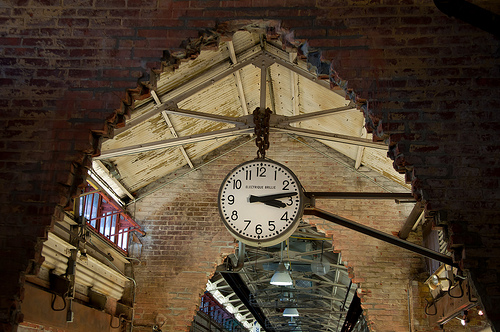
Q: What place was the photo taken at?
A: It was taken at the entrance.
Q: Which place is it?
A: It is an entrance.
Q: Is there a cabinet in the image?
A: No, there are no cabinets.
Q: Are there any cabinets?
A: No, there are no cabinets.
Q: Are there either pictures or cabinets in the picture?
A: No, there are no cabinets or pictures.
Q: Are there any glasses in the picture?
A: No, there are no glasses.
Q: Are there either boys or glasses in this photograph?
A: No, there are no glasses or boys.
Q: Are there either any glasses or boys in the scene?
A: No, there are no glasses or boys.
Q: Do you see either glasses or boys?
A: No, there are no glasses or boys.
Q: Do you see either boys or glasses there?
A: No, there are no glasses or boys.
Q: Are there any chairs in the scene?
A: No, there are no chairs.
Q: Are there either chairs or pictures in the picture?
A: No, there are no chairs or pictures.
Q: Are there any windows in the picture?
A: Yes, there is a window.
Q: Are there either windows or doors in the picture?
A: Yes, there is a window.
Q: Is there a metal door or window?
A: Yes, there is a metal window.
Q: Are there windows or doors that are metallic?
A: Yes, the window is metallic.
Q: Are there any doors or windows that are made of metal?
A: Yes, the window is made of metal.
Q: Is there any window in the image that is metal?
A: Yes, there is a metal window.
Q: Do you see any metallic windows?
A: Yes, there is a metal window.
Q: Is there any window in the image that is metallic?
A: Yes, there is a window that is metallic.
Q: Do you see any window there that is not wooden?
A: Yes, there is a metallic window.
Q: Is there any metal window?
A: Yes, there is a window that is made of metal.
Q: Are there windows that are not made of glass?
A: Yes, there is a window that is made of metal.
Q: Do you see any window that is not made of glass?
A: Yes, there is a window that is made of metal.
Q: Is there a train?
A: No, there are no trains.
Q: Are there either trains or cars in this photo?
A: No, there are no trains or cars.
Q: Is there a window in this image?
A: Yes, there is a window.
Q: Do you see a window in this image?
A: Yes, there is a window.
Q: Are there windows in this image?
A: Yes, there is a window.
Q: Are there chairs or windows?
A: Yes, there is a window.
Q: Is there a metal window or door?
A: Yes, there is a metal window.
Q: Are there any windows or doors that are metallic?
A: Yes, the window is metallic.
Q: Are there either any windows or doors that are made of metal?
A: Yes, the window is made of metal.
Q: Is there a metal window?
A: Yes, there is a window that is made of metal.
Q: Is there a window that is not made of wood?
A: Yes, there is a window that is made of metal.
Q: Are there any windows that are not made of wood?
A: Yes, there is a window that is made of metal.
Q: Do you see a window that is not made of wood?
A: Yes, there is a window that is made of metal.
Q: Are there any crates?
A: No, there are no crates.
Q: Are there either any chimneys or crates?
A: No, there are no crates or chimneys.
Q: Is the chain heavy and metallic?
A: Yes, the chain is heavy and metallic.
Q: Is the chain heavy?
A: Yes, the chain is heavy.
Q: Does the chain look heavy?
A: Yes, the chain is heavy.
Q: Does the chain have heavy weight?
A: Yes, the chain is heavy.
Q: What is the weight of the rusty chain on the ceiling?
A: The chain is heavy.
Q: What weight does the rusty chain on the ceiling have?
A: The chain has heavy weight.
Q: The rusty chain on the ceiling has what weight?
A: The chain is heavy.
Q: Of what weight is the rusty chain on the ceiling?
A: The chain is heavy.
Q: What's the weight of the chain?
A: The chain is heavy.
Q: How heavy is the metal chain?
A: The chain is heavy.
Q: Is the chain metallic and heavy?
A: Yes, the chain is metallic and heavy.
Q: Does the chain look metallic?
A: Yes, the chain is metallic.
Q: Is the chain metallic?
A: Yes, the chain is metallic.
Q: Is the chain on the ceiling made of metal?
A: Yes, the chain is made of metal.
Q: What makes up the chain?
A: The chain is made of metal.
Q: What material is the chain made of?
A: The chain is made of metal.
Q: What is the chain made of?
A: The chain is made of metal.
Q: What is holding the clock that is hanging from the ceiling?
A: The chain is holding the clock.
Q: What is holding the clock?
A: The chain is holding the clock.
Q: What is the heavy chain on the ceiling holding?
A: The chain is holding the clock.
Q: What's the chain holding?
A: The chain is holding the clock.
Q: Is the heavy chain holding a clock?
A: Yes, the chain is holding a clock.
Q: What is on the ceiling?
A: The chain is on the ceiling.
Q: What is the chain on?
A: The chain is on the ceiling.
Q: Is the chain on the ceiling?
A: Yes, the chain is on the ceiling.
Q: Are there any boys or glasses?
A: No, there are no glasses or boys.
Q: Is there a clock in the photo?
A: Yes, there is a clock.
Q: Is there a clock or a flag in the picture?
A: Yes, there is a clock.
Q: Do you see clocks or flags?
A: Yes, there is a clock.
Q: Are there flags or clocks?
A: Yes, there is a clock.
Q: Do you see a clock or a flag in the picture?
A: Yes, there is a clock.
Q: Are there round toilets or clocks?
A: Yes, there is a round clock.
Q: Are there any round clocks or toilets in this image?
A: Yes, there is a round clock.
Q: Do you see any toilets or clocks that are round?
A: Yes, the clock is round.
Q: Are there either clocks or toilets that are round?
A: Yes, the clock is round.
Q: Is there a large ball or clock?
A: Yes, there is a large clock.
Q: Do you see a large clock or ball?
A: Yes, there is a large clock.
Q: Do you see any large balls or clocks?
A: Yes, there is a large clock.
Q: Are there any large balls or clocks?
A: Yes, there is a large clock.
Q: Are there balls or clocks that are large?
A: Yes, the clock is large.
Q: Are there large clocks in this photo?
A: Yes, there is a large clock.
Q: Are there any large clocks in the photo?
A: Yes, there is a large clock.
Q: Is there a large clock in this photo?
A: Yes, there is a large clock.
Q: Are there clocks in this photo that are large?
A: Yes, there is a clock that is large.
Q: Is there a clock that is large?
A: Yes, there is a clock that is large.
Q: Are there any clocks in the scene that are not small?
A: Yes, there is a large clock.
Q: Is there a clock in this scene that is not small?
A: Yes, there is a large clock.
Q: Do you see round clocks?
A: Yes, there is a round clock.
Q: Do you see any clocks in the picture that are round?
A: Yes, there is a clock that is round.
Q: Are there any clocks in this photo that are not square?
A: Yes, there is a round clock.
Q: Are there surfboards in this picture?
A: No, there are no surfboards.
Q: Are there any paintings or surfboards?
A: No, there are no surfboards or paintings.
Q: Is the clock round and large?
A: Yes, the clock is round and large.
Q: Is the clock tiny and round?
A: No, the clock is round but large.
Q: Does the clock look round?
A: Yes, the clock is round.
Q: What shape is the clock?
A: The clock is round.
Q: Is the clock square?
A: No, the clock is round.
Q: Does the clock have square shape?
A: No, the clock is round.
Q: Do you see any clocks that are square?
A: No, there is a clock but it is round.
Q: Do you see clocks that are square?
A: No, there is a clock but it is round.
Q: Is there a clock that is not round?
A: No, there is a clock but it is round.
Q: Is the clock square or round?
A: The clock is round.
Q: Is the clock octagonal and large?
A: No, the clock is large but round.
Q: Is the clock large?
A: Yes, the clock is large.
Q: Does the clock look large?
A: Yes, the clock is large.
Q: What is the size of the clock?
A: The clock is large.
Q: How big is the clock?
A: The clock is large.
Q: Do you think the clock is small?
A: No, the clock is large.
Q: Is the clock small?
A: No, the clock is large.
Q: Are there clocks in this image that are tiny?
A: No, there is a clock but it is large.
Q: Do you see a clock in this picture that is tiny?
A: No, there is a clock but it is large.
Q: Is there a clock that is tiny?
A: No, there is a clock but it is large.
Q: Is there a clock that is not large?
A: No, there is a clock but it is large.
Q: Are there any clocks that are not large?
A: No, there is a clock but it is large.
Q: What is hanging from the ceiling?
A: The clock is hanging from the ceiling.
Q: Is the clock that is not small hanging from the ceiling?
A: Yes, the clock is hanging from the ceiling.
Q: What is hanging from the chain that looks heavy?
A: The clock is hanging from the chain.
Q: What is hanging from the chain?
A: The clock is hanging from the chain.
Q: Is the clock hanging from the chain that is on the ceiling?
A: Yes, the clock is hanging from the chain.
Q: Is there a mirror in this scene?
A: No, there are no mirrors.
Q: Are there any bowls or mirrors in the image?
A: No, there are no mirrors or bowls.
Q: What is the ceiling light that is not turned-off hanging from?
A: The ceiling light is hanging from the ceiling.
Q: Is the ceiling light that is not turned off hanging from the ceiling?
A: Yes, the ceiling light is hanging from the ceiling.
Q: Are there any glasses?
A: No, there are no glasses.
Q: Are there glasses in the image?
A: No, there are no glasses.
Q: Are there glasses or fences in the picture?
A: No, there are no glasses or fences.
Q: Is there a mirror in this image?
A: No, there are no mirrors.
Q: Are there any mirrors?
A: No, there are no mirrors.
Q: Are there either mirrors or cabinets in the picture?
A: No, there are no mirrors or cabinets.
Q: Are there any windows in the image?
A: Yes, there is a window.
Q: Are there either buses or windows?
A: Yes, there is a window.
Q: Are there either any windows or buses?
A: Yes, there is a window.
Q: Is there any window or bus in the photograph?
A: Yes, there is a window.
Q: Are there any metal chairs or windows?
A: Yes, there is a metal window.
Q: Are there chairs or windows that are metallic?
A: Yes, the window is metallic.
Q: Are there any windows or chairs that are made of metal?
A: Yes, the window is made of metal.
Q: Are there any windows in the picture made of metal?
A: Yes, there is a window that is made of metal.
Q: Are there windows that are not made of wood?
A: Yes, there is a window that is made of metal.